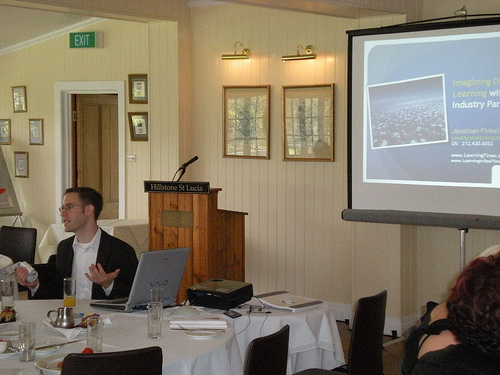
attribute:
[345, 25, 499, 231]
screen — projecter, portable, large, on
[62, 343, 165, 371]
chair — banquet, black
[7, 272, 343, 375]
table — white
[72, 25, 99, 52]
sign — exit, green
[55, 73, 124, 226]
door — white, wooden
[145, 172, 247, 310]
podium — speakers, wooden, brown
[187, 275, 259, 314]
projecter — black, image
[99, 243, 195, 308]
laptop — computer, grey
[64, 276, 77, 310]
juice — orange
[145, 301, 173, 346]
glass — drinking, empty, juice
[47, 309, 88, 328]
pitcher — silver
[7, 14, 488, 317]
walls — yellow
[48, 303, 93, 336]
cup — creamer